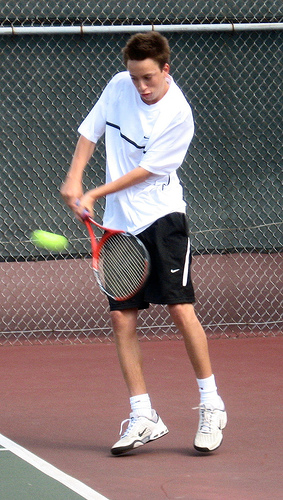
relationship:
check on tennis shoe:
[135, 425, 150, 435] [112, 409, 172, 452]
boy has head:
[60, 31, 228, 456] [125, 27, 169, 104]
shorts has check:
[102, 211, 196, 311] [166, 264, 182, 276]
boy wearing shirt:
[60, 31, 228, 456] [76, 68, 196, 238]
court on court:
[1, 0, 280, 499] [1, 0, 280, 499]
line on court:
[0, 434, 106, 498] [1, 0, 280, 499]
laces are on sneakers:
[114, 411, 142, 440] [109, 408, 174, 458]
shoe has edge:
[109, 408, 169, 456] [111, 436, 147, 454]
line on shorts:
[180, 232, 194, 290] [102, 211, 196, 311]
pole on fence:
[0, 20, 281, 41] [0, 2, 281, 344]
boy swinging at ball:
[60, 31, 228, 456] [27, 228, 67, 258]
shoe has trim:
[109, 408, 169, 456] [112, 422, 227, 456]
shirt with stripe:
[82, 74, 190, 244] [110, 104, 148, 160]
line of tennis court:
[0, 434, 106, 498] [5, 343, 266, 498]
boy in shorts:
[60, 31, 228, 456] [93, 209, 196, 300]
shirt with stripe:
[82, 74, 190, 244] [85, 111, 155, 156]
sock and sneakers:
[128, 392, 155, 419] [113, 404, 168, 456]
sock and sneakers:
[195, 373, 224, 407] [188, 395, 229, 458]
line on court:
[0, 434, 106, 498] [16, 366, 131, 495]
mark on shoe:
[133, 426, 148, 437] [101, 413, 169, 455]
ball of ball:
[27, 228, 67, 258] [18, 208, 73, 259]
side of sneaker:
[110, 416, 198, 448] [95, 400, 182, 470]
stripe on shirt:
[104, 110, 175, 170] [75, 63, 224, 238]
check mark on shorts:
[169, 267, 178, 272] [102, 211, 196, 311]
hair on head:
[124, 30, 172, 71] [126, 32, 169, 101]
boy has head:
[60, 31, 228, 456] [126, 32, 169, 101]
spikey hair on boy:
[123, 28, 169, 66] [58, 30, 228, 456]